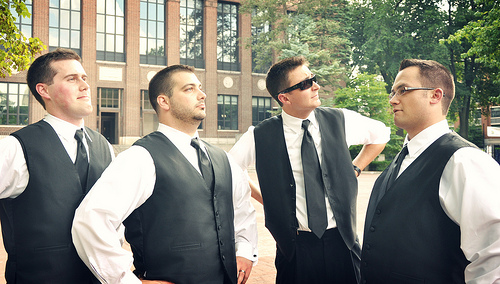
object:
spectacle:
[272, 73, 319, 93]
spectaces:
[383, 79, 452, 101]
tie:
[187, 138, 218, 194]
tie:
[70, 128, 97, 191]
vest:
[2, 117, 118, 283]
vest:
[249, 107, 370, 259]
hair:
[27, 50, 85, 110]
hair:
[149, 65, 196, 111]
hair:
[263, 57, 307, 106]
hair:
[401, 55, 458, 114]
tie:
[299, 119, 336, 241]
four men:
[0, 49, 499, 284]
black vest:
[127, 132, 239, 283]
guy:
[228, 58, 393, 283]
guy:
[68, 64, 260, 283]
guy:
[0, 47, 121, 283]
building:
[0, 0, 353, 164]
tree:
[246, 0, 499, 172]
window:
[183, 0, 245, 72]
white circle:
[256, 79, 266, 90]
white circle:
[223, 77, 235, 89]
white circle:
[145, 69, 155, 81]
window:
[94, 0, 125, 67]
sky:
[349, 0, 459, 15]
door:
[96, 87, 121, 144]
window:
[48, 0, 87, 60]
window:
[138, 0, 172, 67]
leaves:
[237, 0, 499, 170]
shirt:
[359, 121, 500, 283]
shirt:
[225, 103, 392, 235]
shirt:
[70, 122, 268, 284]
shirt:
[0, 114, 120, 201]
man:
[359, 58, 500, 283]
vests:
[363, 133, 480, 283]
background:
[0, 0, 499, 169]